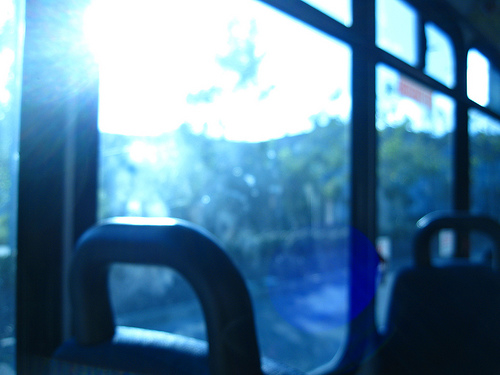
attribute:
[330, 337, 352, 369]
grommet — rubber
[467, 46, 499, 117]
window — small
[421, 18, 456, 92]
window — small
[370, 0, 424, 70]
window — small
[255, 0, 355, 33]
window — small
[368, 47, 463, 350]
window — small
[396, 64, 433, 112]
sticker — red and white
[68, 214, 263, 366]
headrest — black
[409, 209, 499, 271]
headrest — black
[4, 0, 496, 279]
window — sunlit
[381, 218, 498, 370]
bus seat — black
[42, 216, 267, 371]
bus seat — black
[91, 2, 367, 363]
window — large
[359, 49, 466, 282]
window — large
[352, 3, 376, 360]
metal — black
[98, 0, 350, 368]
window — sunlit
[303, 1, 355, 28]
smaller windows — small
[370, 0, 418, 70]
smaller windows — small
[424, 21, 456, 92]
smaller windows — small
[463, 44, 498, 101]
smaller windows — small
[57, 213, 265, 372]
seat — black